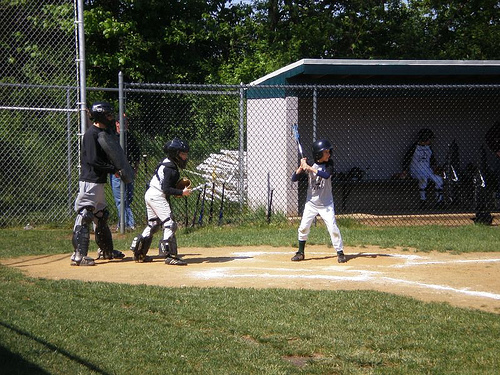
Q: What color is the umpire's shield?
A: Black.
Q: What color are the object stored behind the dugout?
A: White.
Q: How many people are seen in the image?
A: Four.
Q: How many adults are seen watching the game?
A: One.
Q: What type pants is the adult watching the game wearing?
A: Blue jeans.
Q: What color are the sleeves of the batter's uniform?
A: Blue.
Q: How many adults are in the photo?
A: Two.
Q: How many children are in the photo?
A: Three.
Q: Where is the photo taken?
A: On a baseball field.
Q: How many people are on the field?
A: Three.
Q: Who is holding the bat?
A: A boy.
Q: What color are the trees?
A: Green.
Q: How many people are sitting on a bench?
A: One.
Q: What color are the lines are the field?
A: White.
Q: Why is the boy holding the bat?
A: Because he is trying to hit the ball.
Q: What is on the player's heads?
A: Helmets.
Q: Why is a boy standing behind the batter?
A: He is trying to catch the ball.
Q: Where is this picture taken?
A: A baseball field.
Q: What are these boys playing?
A: Baseball.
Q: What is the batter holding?
A: A bat.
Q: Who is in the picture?
A: Males.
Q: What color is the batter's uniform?
A: White.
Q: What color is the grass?
A: Green.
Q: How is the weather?
A: Sunny.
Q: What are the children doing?
A: Playing baseball.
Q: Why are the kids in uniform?
A: They are on a baseball team.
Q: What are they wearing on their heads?
A: Helmets.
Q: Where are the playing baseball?
A: At a baseball diamond.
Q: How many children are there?
A: Three.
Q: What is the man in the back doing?
A: Being the umpire.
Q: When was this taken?
A: Daytime.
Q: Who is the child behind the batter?
A: The catcher.